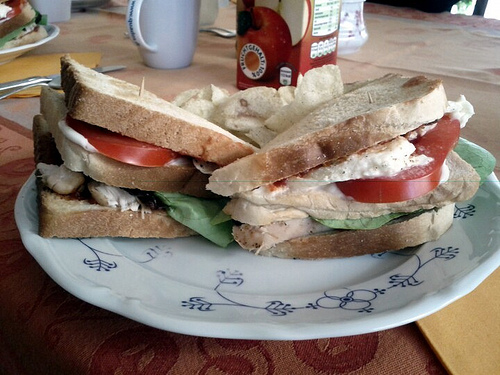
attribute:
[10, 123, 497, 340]
plate — porcelain, white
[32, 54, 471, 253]
food — sitting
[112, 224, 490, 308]
cup — white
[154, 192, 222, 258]
lettuce — green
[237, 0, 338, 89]
juice — boxed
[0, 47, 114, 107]
napkin — yellow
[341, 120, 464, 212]
tomato — sliced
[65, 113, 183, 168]
tomato — sliced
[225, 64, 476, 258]
sandwich — loaded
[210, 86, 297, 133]
chips — potato, yellow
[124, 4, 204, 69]
cup — white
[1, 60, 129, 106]
knife — laying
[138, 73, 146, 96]
toothpick — light brown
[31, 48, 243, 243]
sandwich — half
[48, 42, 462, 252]
sandwiches — loaded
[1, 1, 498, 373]
table — under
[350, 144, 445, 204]
tomato — sliced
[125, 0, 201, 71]
coffee cup — white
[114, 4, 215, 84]
mug — white ceramic 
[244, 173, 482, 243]
chicken — white